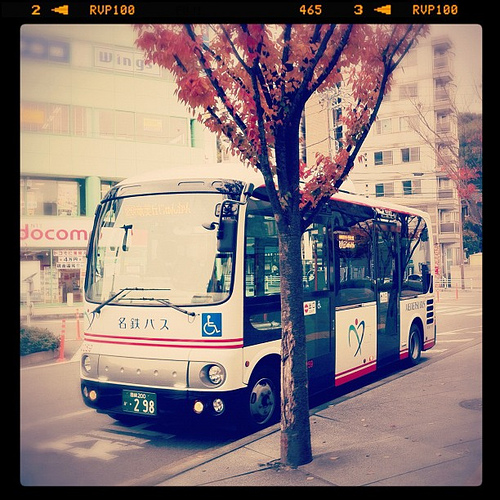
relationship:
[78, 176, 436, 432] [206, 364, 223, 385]
bus has a headlight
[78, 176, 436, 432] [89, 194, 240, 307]
bus has a windshield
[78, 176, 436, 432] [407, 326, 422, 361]
bus has a wheel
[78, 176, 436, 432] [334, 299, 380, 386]
bus has an ad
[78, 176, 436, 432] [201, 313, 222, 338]
bus for handicapped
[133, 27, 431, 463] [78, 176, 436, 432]
tree next to a bus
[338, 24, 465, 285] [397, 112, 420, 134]
building has a window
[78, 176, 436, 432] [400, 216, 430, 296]
bus has a window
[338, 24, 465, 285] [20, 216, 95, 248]
building has a sign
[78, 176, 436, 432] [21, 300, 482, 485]
bus on street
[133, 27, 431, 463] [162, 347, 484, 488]
tree on sidewalk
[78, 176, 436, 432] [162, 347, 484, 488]
bus next to sidewalk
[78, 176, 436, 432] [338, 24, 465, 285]
bus in front of a building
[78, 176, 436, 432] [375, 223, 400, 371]
bus has a door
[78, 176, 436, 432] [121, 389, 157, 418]
bus has a license plate